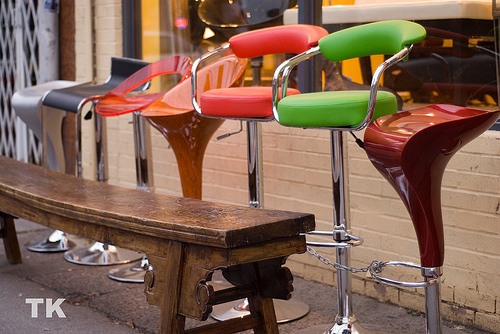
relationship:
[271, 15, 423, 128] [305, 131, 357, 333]
chair on post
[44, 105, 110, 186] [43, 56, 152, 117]
chrome on chair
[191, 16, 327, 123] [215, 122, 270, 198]
chair has chrome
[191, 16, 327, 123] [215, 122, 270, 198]
chair on chrome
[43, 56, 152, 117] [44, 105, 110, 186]
chair has chrome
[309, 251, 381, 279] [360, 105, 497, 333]
chain on stool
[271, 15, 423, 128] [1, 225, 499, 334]
chair on sidewalk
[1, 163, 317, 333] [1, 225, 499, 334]
bench on sidewalk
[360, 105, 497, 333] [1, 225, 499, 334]
stool on sidewalk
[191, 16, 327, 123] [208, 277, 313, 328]
chair on chrome base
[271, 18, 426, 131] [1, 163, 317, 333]
chair behind a bench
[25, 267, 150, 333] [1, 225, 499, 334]
lines in sidewalk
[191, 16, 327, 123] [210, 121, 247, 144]
chair has adjustment lever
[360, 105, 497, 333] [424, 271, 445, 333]
stool on pole